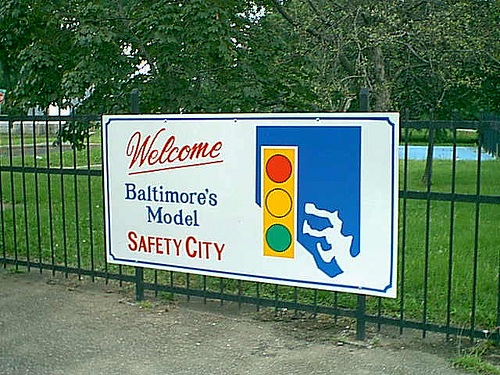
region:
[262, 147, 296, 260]
A traffic light on the sign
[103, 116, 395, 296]
A sign on a fence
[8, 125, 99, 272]
A black fence behind the sign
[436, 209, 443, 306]
Grass behind the black fence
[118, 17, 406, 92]
Trees behind the sign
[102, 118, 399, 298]
A Welcome sign on the fence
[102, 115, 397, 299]
The sign has a rectangular shape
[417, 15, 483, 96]
Leaves on the tree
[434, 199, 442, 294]
Green grass below the tree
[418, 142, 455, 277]
The bars on the fence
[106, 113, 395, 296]
sign attached to fence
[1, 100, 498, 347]
green iron rail fence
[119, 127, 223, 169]
red welcome on sign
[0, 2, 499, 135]
tree with green leaves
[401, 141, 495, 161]
pond next to grass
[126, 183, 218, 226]
blue words on sign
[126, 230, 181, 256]
red safety on sign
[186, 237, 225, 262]
red city on sign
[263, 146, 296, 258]
stop light on sign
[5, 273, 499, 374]
grey concrete side walk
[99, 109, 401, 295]
the sign on the green metal fence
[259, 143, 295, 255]
the picture of the traffic light on the sign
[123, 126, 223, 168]
the word "Welcome" on the sign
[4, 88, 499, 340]
the green metal fence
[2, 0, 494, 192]
the trees behind the fence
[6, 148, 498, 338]
the grass on the ground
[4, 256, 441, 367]
the cement on the ground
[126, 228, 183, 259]
the word "SAFETY" on the sign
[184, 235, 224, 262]
the word "CITY" on the sign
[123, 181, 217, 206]
the word "Baltimore's" on the sign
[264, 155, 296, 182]
red circle on sign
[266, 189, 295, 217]
yellow circle on sign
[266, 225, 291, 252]
green circle on sign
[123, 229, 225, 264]
words "safety city" in red letters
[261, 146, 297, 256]
picture of stop light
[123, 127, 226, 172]
the word "welcome" in red letters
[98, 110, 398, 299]
large white welcome sign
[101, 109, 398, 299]
large white metal sign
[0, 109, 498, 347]
large black metal sign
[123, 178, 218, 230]
blue writing on white sign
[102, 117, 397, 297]
a white sign with red and blue lettering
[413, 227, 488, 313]
green grass of the ground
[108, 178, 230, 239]
blue lettering on the sign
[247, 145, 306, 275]
a picture of a stoplight on a sign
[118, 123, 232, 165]
red cursive lettering on the sign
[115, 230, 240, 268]
red print lettering on the sign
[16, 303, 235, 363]
black asphalt of the path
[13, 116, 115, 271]
black metal fence surrounding the park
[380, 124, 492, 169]
a swimming pool behind the fence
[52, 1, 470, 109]
trees growing behind the fence